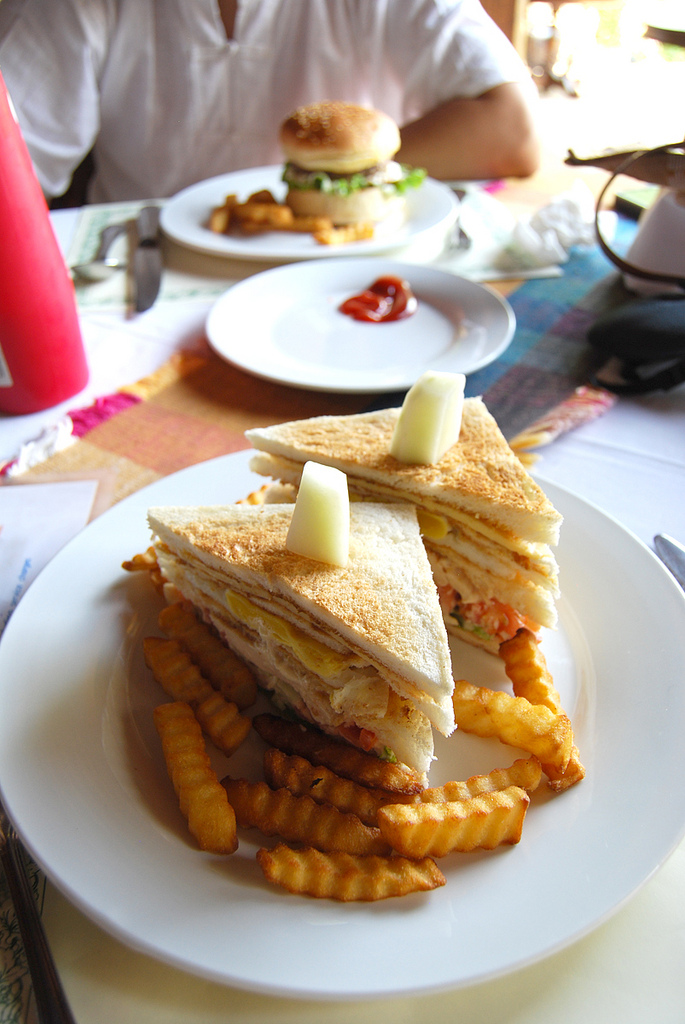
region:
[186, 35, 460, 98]
there is a man wearing white top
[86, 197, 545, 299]
There is a spoon,fork and knife infront of the man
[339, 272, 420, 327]
shiny red glob of ketchup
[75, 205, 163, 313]
spoon and knife on a place mat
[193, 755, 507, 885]
krinkle cut french fries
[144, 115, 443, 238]
small burger and fries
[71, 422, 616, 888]
sandwich with french fries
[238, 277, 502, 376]
ketchup on a plate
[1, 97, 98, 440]
part of a ketchup bottle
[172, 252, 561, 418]
white plate used for ketchup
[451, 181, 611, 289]
napkin on top of table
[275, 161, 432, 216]
lettuce inside of burger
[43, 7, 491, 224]
A person is wearing a white shirt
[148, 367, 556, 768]
Two sandwiches are on a plate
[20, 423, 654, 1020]
A plate is round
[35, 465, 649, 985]
The plate is white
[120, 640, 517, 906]
French fries are on a plate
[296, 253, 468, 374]
Red ketchup on a small plate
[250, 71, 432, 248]
A burger on a plate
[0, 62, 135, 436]
A red ketchup bottle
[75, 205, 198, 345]
A spoon and a knife next to each other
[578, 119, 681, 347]
A bag's strap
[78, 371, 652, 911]
sandwich and french fries on plate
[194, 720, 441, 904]
crinkle cut french fries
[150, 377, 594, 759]
sandwich cut in half diagonally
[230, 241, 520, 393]
plate with ketchup on it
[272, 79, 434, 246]
hamburger on large bun with lettuce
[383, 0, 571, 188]
man sitting with elbow on table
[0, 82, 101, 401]
side of a ketchup bottle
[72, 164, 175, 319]
knife and spoon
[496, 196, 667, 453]
plaid patterned plate mat under plates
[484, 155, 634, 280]
crumpled napkin on the table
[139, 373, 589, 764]
Two identical sandwiches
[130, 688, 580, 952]
French fries on a plate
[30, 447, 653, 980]
A round white plate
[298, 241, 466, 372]
Red ketchup on a plate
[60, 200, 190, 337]
A spoon and a knife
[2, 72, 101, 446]
Red ketchup bottle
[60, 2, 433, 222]
Person wearing a white shirt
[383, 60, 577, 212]
Person's elbow on the table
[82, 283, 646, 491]
A colorful tablecloth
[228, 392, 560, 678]
Triple Decker sandwich plate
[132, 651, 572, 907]
Crispy crinkle cut french fries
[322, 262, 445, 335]
Dollop of ketchup on plate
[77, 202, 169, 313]
Spoon and knife right side plate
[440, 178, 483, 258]
Fork left of plate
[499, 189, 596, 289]
Crumpled up used napkin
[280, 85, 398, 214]
Big burger with fixings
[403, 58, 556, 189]
Elbow placed on table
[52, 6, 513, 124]
White shirt on customer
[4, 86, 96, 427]
Tall red drinking bottle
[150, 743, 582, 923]
A bunch of crinkle-cut french fries.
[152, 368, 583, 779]
A sandwich cut in half.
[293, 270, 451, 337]
A plate of ketchup.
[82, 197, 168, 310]
A Knife and spoon.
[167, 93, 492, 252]
A burger and fries.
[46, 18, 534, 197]
A person in a white shirt.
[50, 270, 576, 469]
A colorful table runner.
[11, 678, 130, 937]
A white porcelain plate.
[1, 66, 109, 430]
A red object on table.